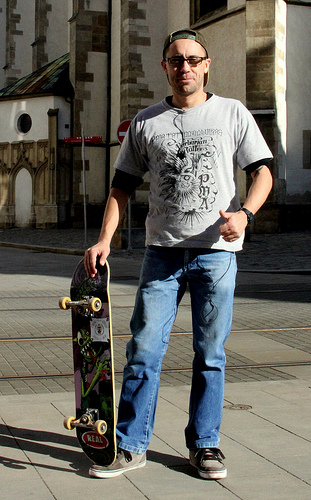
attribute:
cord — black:
[195, 250, 237, 327]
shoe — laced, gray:
[185, 444, 229, 482]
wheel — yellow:
[58, 295, 72, 312]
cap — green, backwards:
[158, 25, 210, 91]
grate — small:
[222, 399, 254, 415]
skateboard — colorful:
[60, 253, 119, 467]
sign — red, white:
[116, 118, 139, 145]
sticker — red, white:
[80, 430, 111, 452]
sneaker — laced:
[84, 443, 150, 480]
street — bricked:
[2, 243, 310, 498]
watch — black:
[241, 206, 258, 229]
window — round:
[15, 112, 33, 134]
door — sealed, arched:
[8, 162, 35, 230]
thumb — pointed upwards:
[217, 207, 243, 221]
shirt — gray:
[107, 90, 278, 257]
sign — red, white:
[63, 133, 103, 147]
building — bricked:
[2, 3, 310, 238]